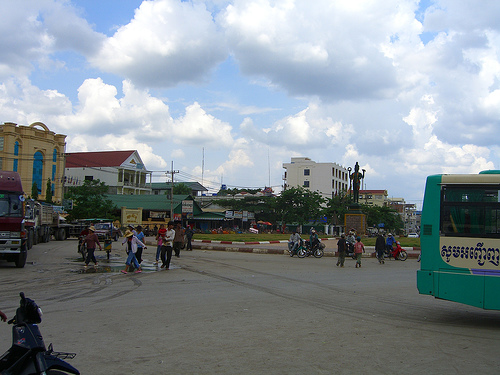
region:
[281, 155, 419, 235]
a row of buildings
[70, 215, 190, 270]
a group of people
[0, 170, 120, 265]
a two trucks and a car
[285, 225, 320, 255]
a two guys on the scooters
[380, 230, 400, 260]
a guy on the red scooter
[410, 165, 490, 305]
the rear end of the bus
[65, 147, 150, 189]
a building with a red roof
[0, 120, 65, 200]
a yellow building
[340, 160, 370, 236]
a statue on a pedestal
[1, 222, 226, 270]
people crossing the road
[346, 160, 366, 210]
statue of man holding two poles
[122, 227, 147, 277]
person walking in white jacket and yellow hat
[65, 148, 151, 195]
white building with red roof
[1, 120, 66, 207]
yellow and blue building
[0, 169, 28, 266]
dark red work truck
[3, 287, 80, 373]
front of black motor scooter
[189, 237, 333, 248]
red and white curb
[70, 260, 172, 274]
small puddle in the street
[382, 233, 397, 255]
person on red scooter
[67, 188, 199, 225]
low building with green roof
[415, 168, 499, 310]
the back of a green and white bus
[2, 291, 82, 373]
the front of a motor scooter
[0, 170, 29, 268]
front left side of burgundy bus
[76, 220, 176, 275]
people walking through puddles of water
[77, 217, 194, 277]
people walking in the street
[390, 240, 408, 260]
the front of a red motor bike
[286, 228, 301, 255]
man sitting on the curb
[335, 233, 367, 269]
two boys walking across the street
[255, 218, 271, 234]
a red umbrella under the tree branches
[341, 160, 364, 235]
monumental statue in the courtyard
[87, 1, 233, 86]
a big fluffy white cloud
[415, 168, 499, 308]
the rear end of a green bus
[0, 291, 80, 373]
the front end of a motor scooter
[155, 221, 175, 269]
an adult carrying a child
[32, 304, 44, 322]
the headlight of a scooter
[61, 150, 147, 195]
a white building with red roof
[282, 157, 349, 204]
a big white building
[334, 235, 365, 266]
a couple walking on the street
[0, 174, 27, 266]
front end of a red bus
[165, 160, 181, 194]
top of a power pole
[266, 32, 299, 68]
part of a cloud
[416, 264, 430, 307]
edge of a bus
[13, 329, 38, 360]
part of a bike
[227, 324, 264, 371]
part of a floor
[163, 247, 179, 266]
part of a trouser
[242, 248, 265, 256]
edge of a road